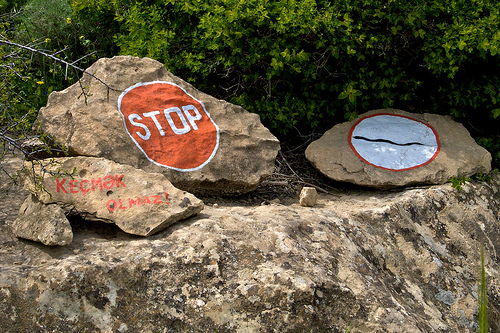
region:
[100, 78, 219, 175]
Round stop sign painted on rock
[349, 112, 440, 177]
Circular red white and black painting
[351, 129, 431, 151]
Snake painted on rock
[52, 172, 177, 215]
Name painted on rocks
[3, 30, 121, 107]
Dead tree branch in frame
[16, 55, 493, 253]
Small rocks on larger rock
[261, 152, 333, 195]
Pile of sticks on rock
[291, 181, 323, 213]
Small rock on larger rock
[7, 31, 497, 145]
Leaf covered trees in background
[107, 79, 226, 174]
Painted round sign with white border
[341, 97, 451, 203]
This is graffiti on stone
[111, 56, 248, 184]
This is graffiti on stone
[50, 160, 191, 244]
This is graffiti on stone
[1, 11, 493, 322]
a pile of rocks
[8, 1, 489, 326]
a pile of brown and tan rock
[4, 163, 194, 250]
writing on a rock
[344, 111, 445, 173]
painting on a rock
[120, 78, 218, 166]
a red and white sign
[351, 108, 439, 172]
a red and white circle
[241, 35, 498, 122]
leafy green bushes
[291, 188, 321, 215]
a small stone on a rock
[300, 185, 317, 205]
a tan stone on a rock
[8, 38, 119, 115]
a bare tree branch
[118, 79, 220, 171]
a painted image of a stop sign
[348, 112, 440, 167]
a painted image of a traffic sign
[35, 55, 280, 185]
a large boulder with a painted stop sign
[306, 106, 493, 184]
a boulder with a traffic sign painted on it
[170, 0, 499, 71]
thick woods in the background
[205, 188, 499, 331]
natural fossilized rock face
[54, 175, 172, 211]
the artist of the strange art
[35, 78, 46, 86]
yellow wild flowers in the woods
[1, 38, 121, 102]
dried up tree branch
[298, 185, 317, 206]
a small rock chip from the boulder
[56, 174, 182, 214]
ROCK HAS FOREIGN WORDS WRITTEN ON IT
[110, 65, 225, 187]
ROCK HAS STOP SIGN PAINTED ON IT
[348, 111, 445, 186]
ROCK HAS CIRCLE WITH RED OUTLINE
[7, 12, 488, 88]
FOLIAGE IN BACK GROUND IS GREEN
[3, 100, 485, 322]
FIVE LITTLE ROCKS ARE ON TOP OF ONE BIG ROCK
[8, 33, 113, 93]
DEAD BRANCH HANGS OVER THE ROCKS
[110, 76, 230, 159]
STOP PAINTING IS RED AND WHITE IN COLOR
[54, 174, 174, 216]
WRITING ON ROCK IS RED IN COLOR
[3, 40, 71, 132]
PLANT HAS YELLOW FLOWERS ON IT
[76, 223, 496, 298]
BIG ROCK IS WHITE, BROWN AND GREY IN COLOR